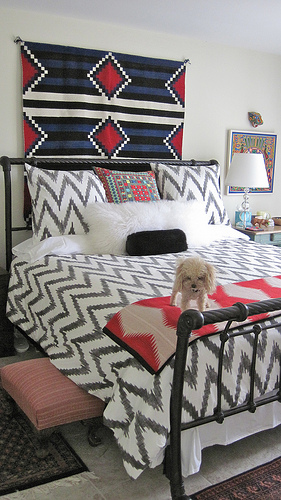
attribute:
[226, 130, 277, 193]
picture — multicolored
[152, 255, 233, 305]
dog — small, white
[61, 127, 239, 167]
headboard — black metal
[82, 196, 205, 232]
white fabric — white 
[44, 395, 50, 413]
chair — edge 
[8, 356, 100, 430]
bench — white, pink 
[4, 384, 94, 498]
rug — dark patterned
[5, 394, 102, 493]
mat — edge 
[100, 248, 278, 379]
blanket — part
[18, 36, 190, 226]
tapestry — multicolored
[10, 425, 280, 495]
tile floor — tiled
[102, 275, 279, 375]
blanket — small, folded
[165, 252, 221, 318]
animal —  head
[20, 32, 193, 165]
fabric — white 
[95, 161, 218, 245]
pillow — black tubular, fluffy white , multi-color 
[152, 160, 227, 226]
pillow — white, gray, zigzag pattern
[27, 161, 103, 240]
pillow — white, gray, zigzag pattern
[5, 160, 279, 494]
bed — edge 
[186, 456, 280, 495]
rug — dark patterned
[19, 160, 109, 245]
pillow — gray, white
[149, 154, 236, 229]
pillow — gray, white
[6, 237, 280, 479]
cover — white 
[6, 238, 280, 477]
blanket — Chevron patterned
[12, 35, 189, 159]
wall hanging — striped, diamond patterned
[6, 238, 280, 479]
comforter — white, gray, zigzag pattern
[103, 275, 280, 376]
fabric — white, red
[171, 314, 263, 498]
artwork — framed 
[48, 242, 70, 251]
fabric — white 